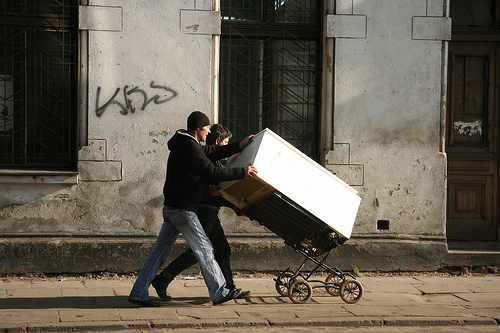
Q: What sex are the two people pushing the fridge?
A: Male.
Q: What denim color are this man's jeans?
A: Blue.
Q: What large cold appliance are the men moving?
A: Fridge.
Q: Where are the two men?
A: On a sidewalk.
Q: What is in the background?
A: A building.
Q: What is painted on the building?
A: Graffiti.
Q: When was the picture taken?
A: During day hours.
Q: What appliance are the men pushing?
A: Refrigerator.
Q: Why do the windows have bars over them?
A: For security.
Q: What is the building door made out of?
A: Wood.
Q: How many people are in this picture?
A: Two.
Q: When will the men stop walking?
A: When they have finished moving the appliance.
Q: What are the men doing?
A: Pushing an appliance down the sidewalk.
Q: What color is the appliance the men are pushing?
A: White.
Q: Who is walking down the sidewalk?
A: Two men.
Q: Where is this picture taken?
A: Outside of a building on a sidewalk.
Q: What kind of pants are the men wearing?
A: Jeans.